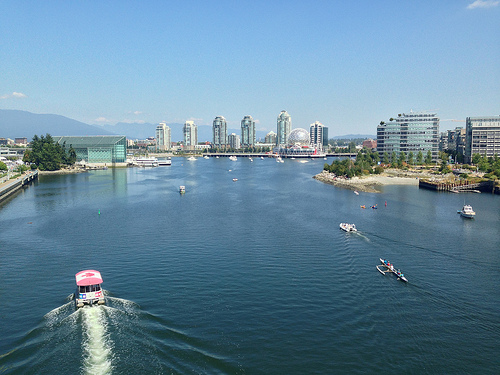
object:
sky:
[0, 2, 499, 141]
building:
[276, 109, 293, 150]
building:
[239, 115, 257, 148]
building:
[213, 115, 228, 148]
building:
[181, 119, 198, 147]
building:
[155, 121, 172, 151]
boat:
[75, 270, 104, 307]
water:
[291, 202, 437, 271]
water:
[45, 297, 140, 374]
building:
[309, 120, 329, 151]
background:
[0, 105, 497, 166]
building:
[14, 138, 27, 145]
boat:
[339, 222, 357, 233]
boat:
[457, 198, 476, 219]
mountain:
[1, 108, 118, 138]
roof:
[76, 269, 103, 286]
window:
[412, 132, 416, 134]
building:
[372, 111, 442, 169]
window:
[388, 131, 393, 133]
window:
[419, 131, 423, 135]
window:
[400, 148, 403, 150]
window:
[424, 140, 427, 141]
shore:
[312, 161, 499, 193]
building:
[462, 116, 500, 168]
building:
[446, 127, 467, 160]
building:
[440, 130, 450, 156]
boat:
[179, 186, 186, 194]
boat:
[186, 156, 197, 160]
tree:
[424, 149, 434, 166]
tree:
[416, 151, 425, 164]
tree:
[406, 151, 413, 170]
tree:
[399, 150, 407, 171]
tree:
[387, 150, 397, 168]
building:
[288, 128, 311, 149]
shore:
[144, 148, 358, 160]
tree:
[67, 142, 80, 169]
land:
[31, 163, 102, 174]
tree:
[59, 140, 69, 165]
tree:
[38, 141, 61, 171]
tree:
[31, 133, 44, 164]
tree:
[22, 148, 33, 169]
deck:
[418, 178, 487, 190]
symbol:
[82, 272, 95, 277]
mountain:
[96, 121, 274, 143]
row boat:
[377, 258, 409, 283]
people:
[399, 272, 405, 277]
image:
[0, 4, 498, 373]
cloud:
[9, 89, 30, 101]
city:
[0, 110, 500, 231]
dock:
[202, 153, 328, 161]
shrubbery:
[324, 151, 384, 178]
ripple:
[108, 293, 140, 310]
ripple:
[112, 304, 170, 320]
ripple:
[123, 319, 187, 339]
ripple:
[33, 298, 78, 319]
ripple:
[56, 310, 87, 326]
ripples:
[411, 283, 456, 308]